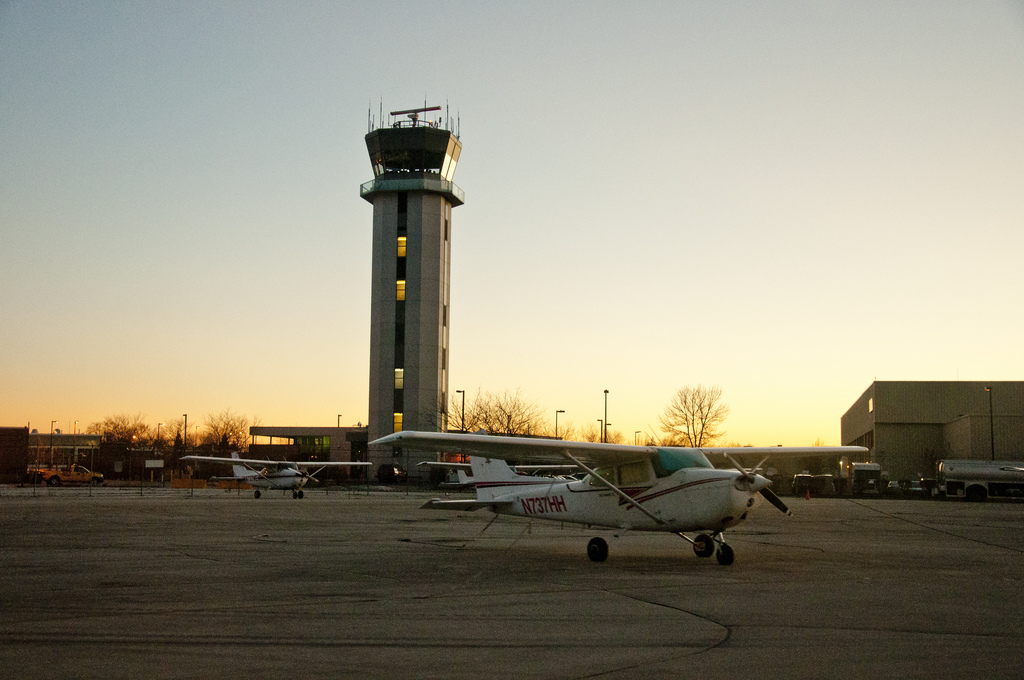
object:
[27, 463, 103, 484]
car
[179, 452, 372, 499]
plane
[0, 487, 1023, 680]
ground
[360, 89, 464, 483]
airplane tower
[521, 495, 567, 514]
numbers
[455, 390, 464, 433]
lamp post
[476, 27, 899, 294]
clouds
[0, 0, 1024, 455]
sky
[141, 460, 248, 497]
fence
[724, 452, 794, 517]
propeller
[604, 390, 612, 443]
light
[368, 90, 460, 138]
antennas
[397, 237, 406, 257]
glass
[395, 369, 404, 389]
glass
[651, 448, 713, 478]
glass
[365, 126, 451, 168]
wall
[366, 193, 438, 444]
wall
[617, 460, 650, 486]
window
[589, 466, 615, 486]
window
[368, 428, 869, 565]
airplane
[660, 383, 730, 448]
tree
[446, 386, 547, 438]
tree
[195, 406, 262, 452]
tree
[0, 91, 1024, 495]
city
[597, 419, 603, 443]
street light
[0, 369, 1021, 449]
terminal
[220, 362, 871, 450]
sun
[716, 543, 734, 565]
landing gear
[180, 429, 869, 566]
planes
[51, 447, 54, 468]
truck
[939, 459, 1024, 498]
truck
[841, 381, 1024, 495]
building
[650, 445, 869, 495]
building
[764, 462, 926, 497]
vehicles